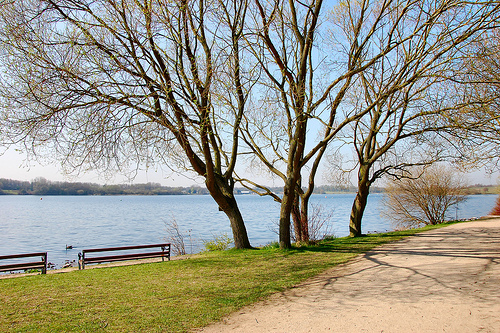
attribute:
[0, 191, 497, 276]
water — large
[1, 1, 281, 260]
tree — large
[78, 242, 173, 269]
bench — wooden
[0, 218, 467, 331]
grass — Green 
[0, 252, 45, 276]
bench — wooden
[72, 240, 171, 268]
bench — wooden 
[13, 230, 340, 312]
grass — green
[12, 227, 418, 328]
grass — Green 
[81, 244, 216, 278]
bench — park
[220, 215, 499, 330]
pavement — grassy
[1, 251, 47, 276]
wooden bench — long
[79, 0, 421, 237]
trees — dried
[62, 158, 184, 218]
trees — Many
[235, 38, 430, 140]
sky — bright, blue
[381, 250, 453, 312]
floor — brown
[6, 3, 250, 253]
trees — large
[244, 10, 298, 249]
trees — large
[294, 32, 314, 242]
trees — large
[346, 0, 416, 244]
trees — large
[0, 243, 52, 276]
bench — park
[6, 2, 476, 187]
sky — blue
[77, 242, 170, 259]
gape — wide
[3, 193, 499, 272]
waves — small